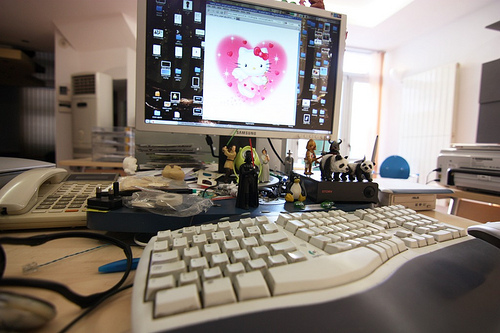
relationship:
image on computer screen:
[201, 6, 295, 124] [134, 2, 341, 142]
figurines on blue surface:
[211, 134, 375, 210] [196, 94, 376, 249]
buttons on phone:
[36, 192, 91, 213] [0, 165, 125, 231]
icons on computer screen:
[152, 27, 166, 57] [134, 2, 341, 142]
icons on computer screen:
[312, 65, 327, 94] [134, 2, 341, 142]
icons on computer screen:
[155, 93, 182, 117] [134, 2, 341, 142]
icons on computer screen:
[310, 27, 334, 58] [134, 2, 341, 142]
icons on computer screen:
[189, 6, 201, 59] [134, 2, 341, 142]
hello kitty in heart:
[230, 44, 268, 99] [216, 34, 288, 107]